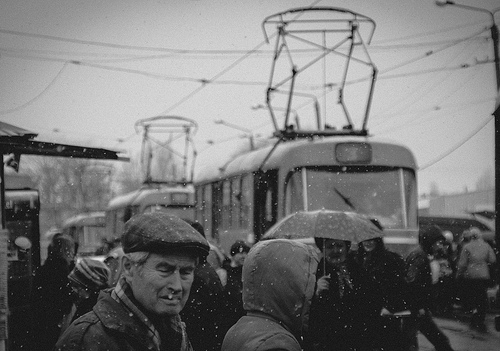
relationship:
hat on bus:
[120, 212, 210, 256] [194, 132, 424, 264]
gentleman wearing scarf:
[78, 182, 220, 332] [101, 279, 331, 332]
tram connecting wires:
[193, 5, 418, 262] [3, 45, 498, 88]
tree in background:
[98, 162, 122, 219] [8, 2, 495, 272]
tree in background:
[70, 155, 96, 214] [8, 2, 495, 272]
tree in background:
[56, 160, 79, 217] [8, 2, 495, 272]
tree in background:
[42, 157, 62, 212] [8, 2, 495, 272]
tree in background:
[112, 149, 142, 194] [8, 2, 495, 272]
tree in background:
[24, 155, 43, 208] [8, 2, 495, 272]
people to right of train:
[423, 223, 493, 338] [169, 126, 421, 260]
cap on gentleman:
[128, 205, 213, 250] [50, 211, 210, 351]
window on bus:
[237, 171, 251, 229] [194, 107, 471, 349]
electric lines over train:
[136, 112, 201, 192] [40, 139, 442, 266]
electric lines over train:
[258, 5, 385, 138] [40, 139, 442, 266]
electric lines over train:
[73, 156, 117, 214] [40, 139, 442, 266]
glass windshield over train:
[303, 169, 423, 200] [24, 142, 447, 317]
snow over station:
[52, 155, 234, 222] [0, 109, 135, 335]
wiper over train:
[332, 178, 391, 223] [36, 114, 484, 302]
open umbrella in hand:
[259, 206, 385, 243] [312, 269, 341, 299]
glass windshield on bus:
[283, 166, 418, 230] [194, 132, 424, 264]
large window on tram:
[213, 180, 233, 231] [193, 4, 418, 256]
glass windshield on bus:
[283, 166, 418, 230] [32, 115, 426, 297]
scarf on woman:
[319, 259, 357, 299] [305, 222, 365, 313]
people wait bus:
[15, 197, 484, 349] [194, 132, 424, 264]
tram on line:
[193, 5, 418, 262] [7, 2, 485, 134]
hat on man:
[120, 209, 210, 252] [59, 203, 205, 348]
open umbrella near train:
[220, 218, 447, 243] [186, 123, 426, 284]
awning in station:
[15, 127, 140, 181] [6, 117, 136, 314]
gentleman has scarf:
[50, 211, 210, 351] [110, 275, 186, 349]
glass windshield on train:
[283, 166, 418, 230] [192, 126, 424, 255]